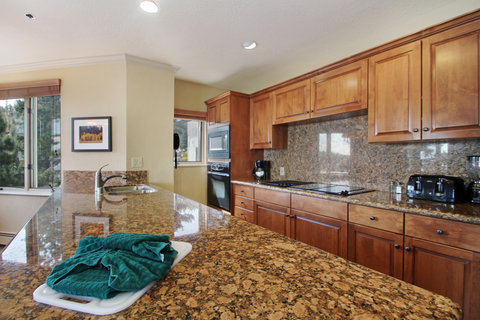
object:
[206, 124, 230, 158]
microwave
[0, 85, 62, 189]
window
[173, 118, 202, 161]
window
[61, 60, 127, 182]
wall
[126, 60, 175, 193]
wall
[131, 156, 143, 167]
outlet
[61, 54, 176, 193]
wall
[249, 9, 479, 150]
cabinets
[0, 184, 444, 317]
counter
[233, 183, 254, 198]
drawer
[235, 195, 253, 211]
drawer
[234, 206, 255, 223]
drawer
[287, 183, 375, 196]
sink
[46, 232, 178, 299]
towel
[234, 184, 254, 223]
drawers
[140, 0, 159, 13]
light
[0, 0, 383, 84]
ceiling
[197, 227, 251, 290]
table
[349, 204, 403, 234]
drawer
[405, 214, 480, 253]
drawer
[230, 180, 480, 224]
counter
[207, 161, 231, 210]
oven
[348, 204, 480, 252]
closed drawers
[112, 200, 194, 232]
tiled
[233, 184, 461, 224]
these